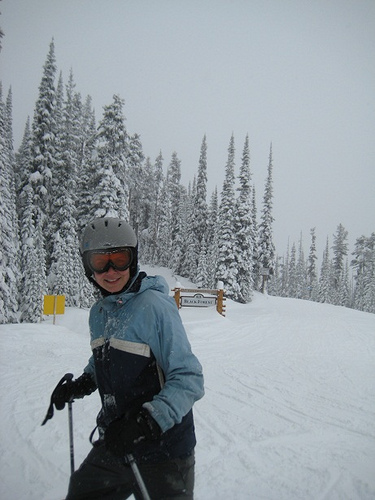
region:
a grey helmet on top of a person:
[76, 216, 132, 255]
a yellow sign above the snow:
[41, 290, 68, 317]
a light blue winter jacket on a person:
[73, 278, 202, 417]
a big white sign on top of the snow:
[169, 282, 230, 312]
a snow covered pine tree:
[223, 185, 258, 298]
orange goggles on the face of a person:
[91, 246, 138, 273]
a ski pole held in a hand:
[42, 369, 83, 474]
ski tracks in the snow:
[215, 343, 371, 464]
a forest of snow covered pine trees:
[7, 85, 372, 308]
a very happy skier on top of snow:
[63, 221, 202, 479]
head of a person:
[65, 200, 152, 308]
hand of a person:
[101, 411, 163, 471]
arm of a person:
[135, 378, 208, 450]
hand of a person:
[54, 377, 85, 411]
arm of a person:
[68, 350, 110, 407]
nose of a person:
[104, 263, 121, 281]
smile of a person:
[101, 279, 134, 291]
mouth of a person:
[96, 267, 127, 290]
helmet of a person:
[80, 203, 140, 253]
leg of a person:
[76, 431, 136, 495]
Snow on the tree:
[258, 134, 273, 294]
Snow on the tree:
[230, 133, 255, 304]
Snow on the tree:
[213, 133, 240, 295]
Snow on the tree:
[188, 132, 208, 271]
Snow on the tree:
[197, 189, 215, 289]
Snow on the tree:
[162, 159, 181, 264]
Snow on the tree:
[302, 224, 321, 297]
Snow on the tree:
[328, 220, 349, 304]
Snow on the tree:
[351, 228, 372, 313]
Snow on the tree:
[278, 235, 297, 299]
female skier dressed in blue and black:
[40, 216, 210, 498]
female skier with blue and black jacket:
[34, 213, 207, 496]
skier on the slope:
[5, 11, 362, 494]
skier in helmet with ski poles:
[39, 210, 206, 497]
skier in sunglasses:
[40, 211, 207, 496]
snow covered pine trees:
[7, 29, 278, 326]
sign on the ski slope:
[171, 273, 235, 319]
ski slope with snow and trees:
[269, 221, 374, 428]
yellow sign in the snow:
[22, 257, 79, 347]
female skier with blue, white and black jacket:
[38, 215, 209, 498]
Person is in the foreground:
[33, 207, 241, 498]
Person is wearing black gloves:
[44, 366, 170, 464]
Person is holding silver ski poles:
[42, 370, 155, 499]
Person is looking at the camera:
[77, 242, 136, 296]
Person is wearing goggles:
[82, 240, 136, 298]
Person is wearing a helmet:
[70, 212, 151, 300]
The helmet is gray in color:
[76, 212, 143, 299]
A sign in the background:
[168, 282, 229, 322]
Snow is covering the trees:
[0, 30, 373, 321]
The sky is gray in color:
[2, 2, 373, 275]